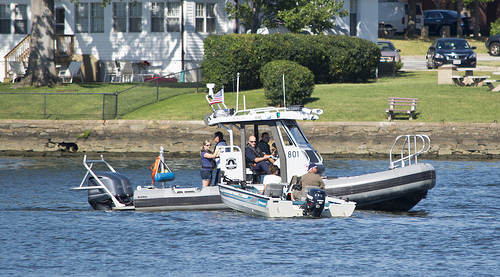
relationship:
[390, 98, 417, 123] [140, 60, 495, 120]
bench on grass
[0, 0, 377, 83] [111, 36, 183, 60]
house has siding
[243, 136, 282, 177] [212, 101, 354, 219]
man in boat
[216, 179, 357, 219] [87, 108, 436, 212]
boat by big boat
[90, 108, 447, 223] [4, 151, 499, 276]
boats on water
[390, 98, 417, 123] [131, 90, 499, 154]
bench on bank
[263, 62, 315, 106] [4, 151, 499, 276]
bush near water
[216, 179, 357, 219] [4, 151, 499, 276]
boat in water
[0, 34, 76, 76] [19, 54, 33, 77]
rails by steps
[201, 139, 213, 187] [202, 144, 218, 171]
woman wearing purple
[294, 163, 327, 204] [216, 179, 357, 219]
man in boat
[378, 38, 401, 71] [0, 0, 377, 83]
car by house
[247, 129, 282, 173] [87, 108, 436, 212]
men in boat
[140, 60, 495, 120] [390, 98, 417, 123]
grass under bench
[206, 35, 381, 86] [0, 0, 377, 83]
hedges by house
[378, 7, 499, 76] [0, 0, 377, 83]
vehicles by house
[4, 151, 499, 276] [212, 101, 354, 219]
water under boat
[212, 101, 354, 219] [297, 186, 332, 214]
boat has engine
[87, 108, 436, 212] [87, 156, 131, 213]
boat has engine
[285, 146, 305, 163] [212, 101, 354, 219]
801 on boat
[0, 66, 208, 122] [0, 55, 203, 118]
fence around yard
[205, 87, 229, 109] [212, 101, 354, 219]
flag on boat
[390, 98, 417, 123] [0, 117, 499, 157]
bench behind wall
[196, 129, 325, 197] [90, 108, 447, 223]
people on boats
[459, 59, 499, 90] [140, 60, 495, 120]
tables on grass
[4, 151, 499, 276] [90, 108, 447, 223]
water under boats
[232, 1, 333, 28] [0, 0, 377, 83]
tree by house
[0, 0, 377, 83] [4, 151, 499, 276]
house beside water